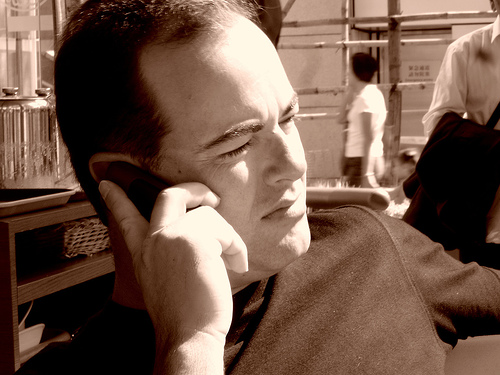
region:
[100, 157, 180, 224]
Cell phone pressed against ear.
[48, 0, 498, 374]
Man using a cell phone.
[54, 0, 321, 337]
Man squinting into the sun.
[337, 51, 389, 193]
Person wearing a black hat.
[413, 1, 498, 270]
Person wearing a white collared shirt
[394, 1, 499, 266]
Person carrying their coat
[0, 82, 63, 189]
Shiny metal canister with design on it.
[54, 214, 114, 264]
A wicker basket tucked away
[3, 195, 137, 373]
Wooden shelf behind a man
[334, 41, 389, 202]
Man in white shirt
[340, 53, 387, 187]
person wearing a white short sleeve shirt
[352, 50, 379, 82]
person wearing a black knit hat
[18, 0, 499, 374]
man has closed eyes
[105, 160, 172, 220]
black phone next to ear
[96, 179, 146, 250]
index finger is extended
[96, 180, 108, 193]
fingernail on top of index finger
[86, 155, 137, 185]
ear beneath cell phone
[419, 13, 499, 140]
white long sleeve dress shirt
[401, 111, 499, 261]
dark jacket hanging from arm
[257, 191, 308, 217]
mouth is closed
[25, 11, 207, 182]
man has dark hair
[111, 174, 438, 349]
man has dark shirt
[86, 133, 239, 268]
man is holding phone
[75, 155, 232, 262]
cell in right hand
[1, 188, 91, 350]
dark back on chair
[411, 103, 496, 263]
person has black bag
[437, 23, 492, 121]
person has white shirt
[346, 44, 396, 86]
person outside has dark hair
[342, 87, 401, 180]
person outside has white shirt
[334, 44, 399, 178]
person outside is walking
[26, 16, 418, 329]
this is a black and white photo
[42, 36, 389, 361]
this picture is gray scale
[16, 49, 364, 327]
this is monochromatic style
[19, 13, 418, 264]
this is a public area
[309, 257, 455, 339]
the man is wearing a long sleeve shirt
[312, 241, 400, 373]
the man's shirt is black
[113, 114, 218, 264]
the man has a phone in his hand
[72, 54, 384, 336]
this is a man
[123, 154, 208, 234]
the man is talking on the phone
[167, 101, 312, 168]
the man has his eyes closed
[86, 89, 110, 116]
man has black hair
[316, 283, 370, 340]
man wearing black shirt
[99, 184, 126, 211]
man finger on phone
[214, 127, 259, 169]
left eye of man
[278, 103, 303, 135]
right eye of man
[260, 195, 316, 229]
mans mouth is closed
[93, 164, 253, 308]
cellphone in mans hand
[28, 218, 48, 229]
brown dresser behind man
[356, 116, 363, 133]
woman wearing white shirt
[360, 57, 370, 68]
woman has short hair